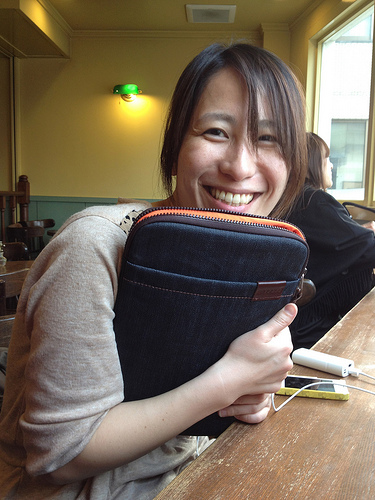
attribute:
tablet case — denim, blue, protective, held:
[113, 207, 309, 436]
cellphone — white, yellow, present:
[276, 373, 349, 400]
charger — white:
[291, 347, 356, 378]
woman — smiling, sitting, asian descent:
[0, 39, 308, 499]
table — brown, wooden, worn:
[148, 285, 374, 499]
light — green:
[111, 84, 144, 102]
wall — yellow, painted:
[0, 30, 293, 201]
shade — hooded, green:
[113, 84, 139, 95]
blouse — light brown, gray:
[0, 201, 208, 499]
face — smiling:
[178, 67, 292, 216]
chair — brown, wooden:
[5, 220, 58, 258]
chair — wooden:
[0, 242, 29, 260]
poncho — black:
[282, 186, 374, 328]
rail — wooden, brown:
[0, 173, 31, 244]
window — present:
[313, 0, 373, 202]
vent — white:
[187, 3, 237, 26]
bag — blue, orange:
[343, 201, 374, 233]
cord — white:
[271, 368, 374, 412]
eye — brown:
[202, 127, 227, 138]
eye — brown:
[256, 134, 276, 142]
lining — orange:
[134, 209, 305, 239]